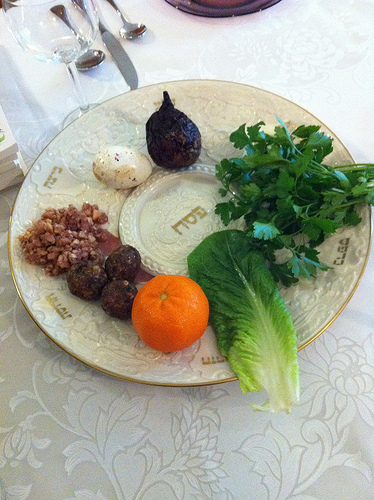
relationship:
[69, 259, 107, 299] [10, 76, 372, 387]
meatball on top of plate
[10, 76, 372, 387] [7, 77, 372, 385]
plate has border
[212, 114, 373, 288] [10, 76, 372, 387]
parsley on top of plate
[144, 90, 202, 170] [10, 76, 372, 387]
fig on top of plate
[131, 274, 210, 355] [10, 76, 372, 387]
orange on top of plate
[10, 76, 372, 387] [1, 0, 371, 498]
plate on top of tablecloth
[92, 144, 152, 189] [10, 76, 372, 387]
egg on top of plate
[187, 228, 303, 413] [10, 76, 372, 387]
romaine lettuce on top of plate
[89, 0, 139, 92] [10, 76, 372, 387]
knife behind plate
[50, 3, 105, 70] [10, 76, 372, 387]
spoon set behind plate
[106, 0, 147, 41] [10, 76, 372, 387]
spoon set behind plate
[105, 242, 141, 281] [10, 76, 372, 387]
meatball on top of plate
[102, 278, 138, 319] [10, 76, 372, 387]
meatball on top of plate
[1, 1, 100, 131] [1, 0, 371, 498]
wine glass on top of tablecloth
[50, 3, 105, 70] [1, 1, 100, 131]
spoon next to wine glass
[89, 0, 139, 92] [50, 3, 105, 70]
knife next to spoon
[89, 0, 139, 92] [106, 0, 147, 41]
knife next to spoon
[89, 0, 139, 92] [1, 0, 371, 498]
knife on top of tablecloth